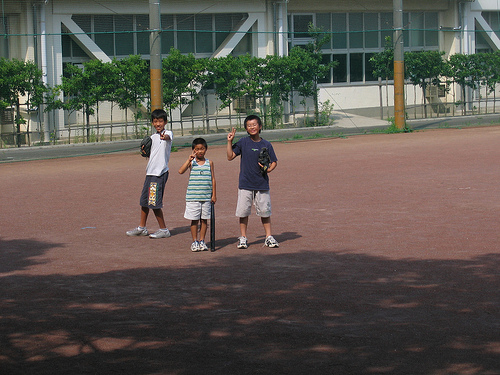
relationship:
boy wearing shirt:
[225, 114, 282, 250] [231, 133, 279, 192]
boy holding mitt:
[123, 107, 173, 240] [139, 133, 154, 161]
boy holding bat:
[179, 137, 220, 255] [208, 196, 216, 255]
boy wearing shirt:
[179, 137, 220, 255] [185, 156, 213, 204]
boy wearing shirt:
[123, 107, 173, 240] [145, 129, 174, 179]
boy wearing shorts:
[123, 107, 173, 240] [139, 167, 170, 212]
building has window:
[1, 1, 500, 148] [71, 14, 95, 60]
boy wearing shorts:
[179, 137, 220, 255] [183, 199, 215, 221]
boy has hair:
[225, 114, 282, 250] [243, 114, 263, 137]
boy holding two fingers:
[225, 114, 282, 250] [224, 125, 239, 144]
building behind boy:
[1, 1, 500, 148] [123, 107, 175, 240]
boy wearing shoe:
[225, 114, 282, 250] [261, 234, 280, 249]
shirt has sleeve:
[231, 133, 279, 192] [265, 143, 280, 168]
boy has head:
[123, 107, 173, 240] [149, 106, 170, 136]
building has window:
[1, 1, 500, 148] [92, 10, 115, 60]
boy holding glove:
[225, 114, 282, 250] [256, 147, 274, 179]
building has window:
[1, 1, 500, 148] [112, 10, 137, 60]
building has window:
[1, 1, 500, 148] [133, 12, 155, 57]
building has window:
[1, 1, 500, 148] [157, 10, 176, 58]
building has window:
[1, 1, 500, 148] [173, 12, 197, 57]